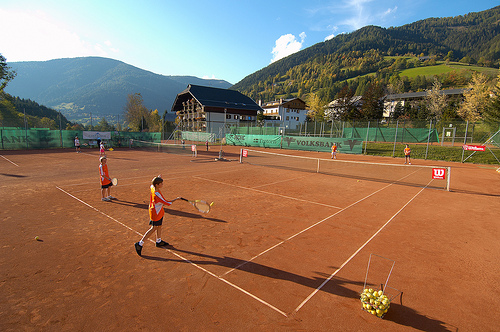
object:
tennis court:
[2, 138, 500, 331]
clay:
[4, 141, 500, 331]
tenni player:
[135, 177, 183, 254]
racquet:
[183, 196, 211, 215]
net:
[241, 147, 451, 188]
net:
[130, 139, 198, 158]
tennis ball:
[210, 201, 215, 205]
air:
[0, 2, 500, 332]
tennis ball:
[35, 235, 41, 241]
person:
[98, 155, 113, 203]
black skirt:
[101, 185, 114, 188]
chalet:
[177, 82, 260, 135]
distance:
[7, 51, 500, 155]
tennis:
[3, 120, 499, 330]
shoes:
[133, 240, 143, 255]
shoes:
[102, 197, 111, 202]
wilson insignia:
[432, 169, 447, 180]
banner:
[222, 135, 364, 148]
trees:
[421, 81, 455, 122]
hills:
[3, 98, 68, 129]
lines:
[61, 192, 117, 225]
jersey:
[101, 163, 112, 187]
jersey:
[149, 189, 173, 221]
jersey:
[404, 148, 410, 155]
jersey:
[331, 145, 337, 153]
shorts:
[148, 217, 164, 229]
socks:
[140, 239, 145, 245]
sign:
[463, 144, 485, 153]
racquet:
[104, 173, 120, 186]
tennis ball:
[354, 177, 364, 184]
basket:
[362, 252, 406, 314]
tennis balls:
[360, 291, 367, 299]